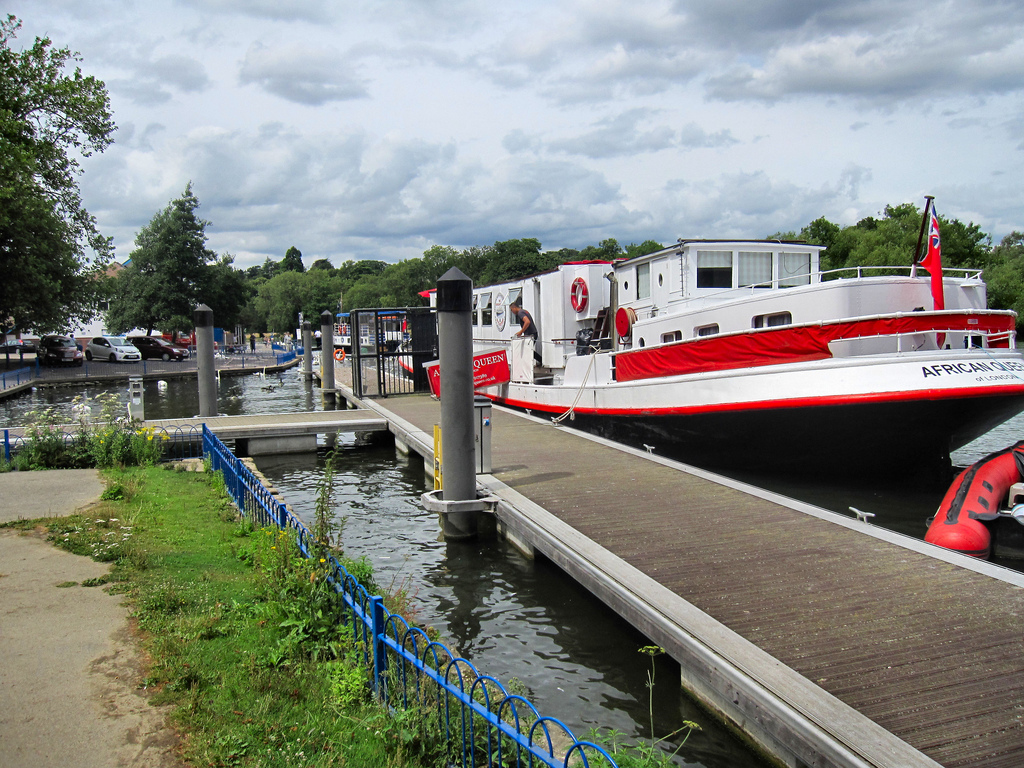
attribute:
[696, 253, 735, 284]
window —   glass,  ship's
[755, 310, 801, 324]
window — glass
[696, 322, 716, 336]
window — glass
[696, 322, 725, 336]
window — glass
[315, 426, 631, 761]
water — a small body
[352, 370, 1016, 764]
boardwalk — wooden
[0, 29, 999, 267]
clouds — grey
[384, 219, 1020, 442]
boat — red and white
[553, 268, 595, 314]
life preserver — red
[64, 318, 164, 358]
car — small white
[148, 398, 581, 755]
metal fence — decorative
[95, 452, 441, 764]
grass — a patch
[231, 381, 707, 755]
water — a body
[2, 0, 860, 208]
sky — overcast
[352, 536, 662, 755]
water — calm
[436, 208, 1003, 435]
boat — parked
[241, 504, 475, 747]
fence — blue